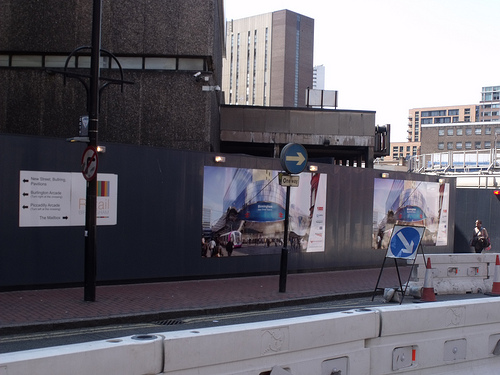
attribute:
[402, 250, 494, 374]
cone — orange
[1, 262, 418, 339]
sidewalk — brick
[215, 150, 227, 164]
light — white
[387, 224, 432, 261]
street sign — blue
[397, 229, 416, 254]
arrow — white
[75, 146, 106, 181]
sign — red, white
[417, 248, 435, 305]
cone — ORANGE, WHITE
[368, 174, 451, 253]
poster — larger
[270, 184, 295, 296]
pole — black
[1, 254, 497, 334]
sidewalk — red, cobblestone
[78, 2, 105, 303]
post — metal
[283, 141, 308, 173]
blue sign — white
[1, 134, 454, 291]
barrier — gray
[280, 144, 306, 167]
arrow — WHITE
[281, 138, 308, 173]
sign — blue, white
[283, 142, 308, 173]
sign — blue, white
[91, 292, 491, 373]
barricade — white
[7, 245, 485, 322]
sidewalk — brick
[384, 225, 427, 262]
sign — blue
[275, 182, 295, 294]
post — black, iron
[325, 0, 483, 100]
sky — clear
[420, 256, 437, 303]
cones — orange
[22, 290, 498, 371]
construction barrier — white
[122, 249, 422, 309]
sidewalk — brown, brick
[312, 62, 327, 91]
building — white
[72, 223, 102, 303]
bottom — black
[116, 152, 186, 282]
wall — white, temporary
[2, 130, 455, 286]
wall — gray